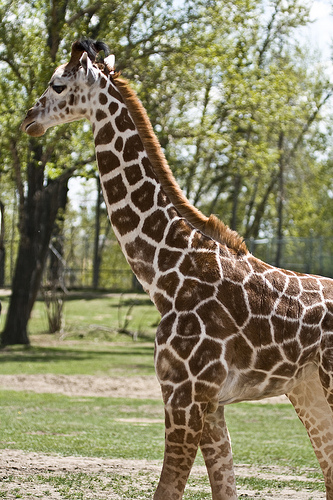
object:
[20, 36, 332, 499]
giraffe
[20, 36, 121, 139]
head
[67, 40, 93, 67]
horns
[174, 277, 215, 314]
spot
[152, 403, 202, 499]
legs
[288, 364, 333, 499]
hind legs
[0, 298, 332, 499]
road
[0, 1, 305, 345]
tree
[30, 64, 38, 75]
leaves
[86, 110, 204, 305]
neck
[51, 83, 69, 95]
eye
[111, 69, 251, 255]
mane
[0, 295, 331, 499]
grass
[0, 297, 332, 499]
ground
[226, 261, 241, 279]
fur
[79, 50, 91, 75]
ear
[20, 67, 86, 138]
face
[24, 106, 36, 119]
snout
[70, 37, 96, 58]
fur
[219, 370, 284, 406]
stomach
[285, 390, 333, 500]
edge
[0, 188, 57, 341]
tree trunk